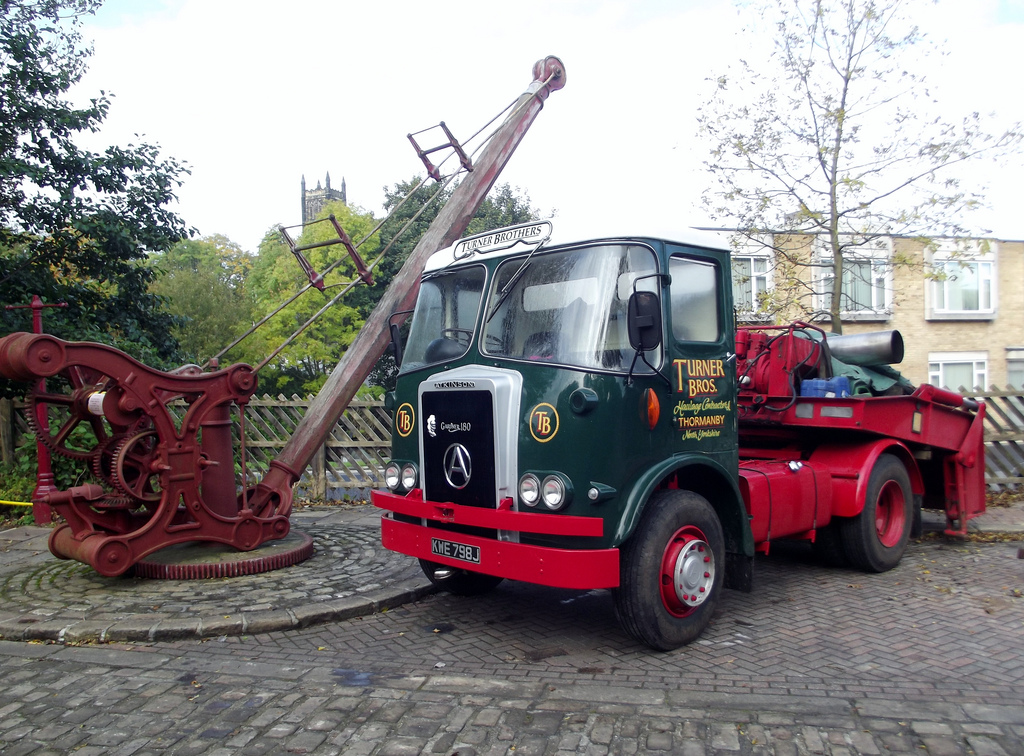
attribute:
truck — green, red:
[362, 214, 993, 662]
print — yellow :
[671, 353, 726, 401]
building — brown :
[677, 198, 1021, 462]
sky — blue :
[5, 4, 1023, 240]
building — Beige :
[636, 183, 1023, 445]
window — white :
[798, 228, 891, 319]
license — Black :
[433, 537, 486, 570]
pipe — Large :
[813, 332, 909, 369]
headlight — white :
[375, 459, 412, 492]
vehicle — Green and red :
[379, 211, 972, 622]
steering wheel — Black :
[437, 315, 507, 361]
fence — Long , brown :
[20, 353, 1017, 531]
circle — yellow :
[392, 403, 421, 434]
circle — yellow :
[522, 397, 564, 445]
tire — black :
[614, 475, 738, 650]